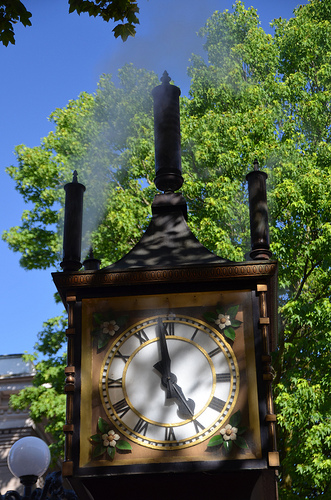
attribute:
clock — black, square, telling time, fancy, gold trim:
[237, 436, 284, 483]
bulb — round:
[8, 437, 52, 483]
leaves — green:
[201, 76, 268, 116]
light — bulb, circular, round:
[6, 423, 47, 446]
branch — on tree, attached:
[300, 254, 321, 292]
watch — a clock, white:
[116, 332, 242, 420]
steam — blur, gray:
[103, 74, 106, 228]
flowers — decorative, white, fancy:
[210, 290, 234, 330]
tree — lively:
[205, 73, 318, 207]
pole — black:
[151, 79, 183, 181]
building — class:
[4, 381, 33, 448]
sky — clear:
[24, 17, 234, 75]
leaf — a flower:
[228, 328, 235, 339]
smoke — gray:
[97, 66, 141, 201]